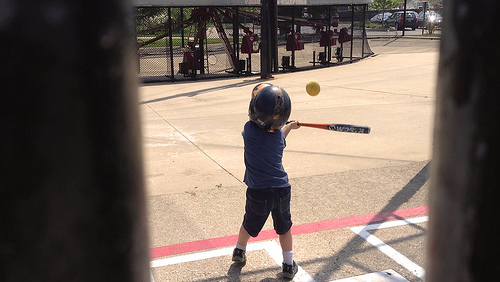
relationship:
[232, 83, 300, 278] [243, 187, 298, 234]
boy wearing shorts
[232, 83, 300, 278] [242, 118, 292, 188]
boy wearing shirt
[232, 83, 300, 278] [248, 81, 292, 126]
boy has helmet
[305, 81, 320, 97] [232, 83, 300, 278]
ball near boy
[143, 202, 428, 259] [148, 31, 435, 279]
line on ground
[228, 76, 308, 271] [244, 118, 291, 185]
boy has shirt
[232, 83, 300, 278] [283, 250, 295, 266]
boy has sock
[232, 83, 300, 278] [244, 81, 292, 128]
boy has helmet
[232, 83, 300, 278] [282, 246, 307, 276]
boy has socks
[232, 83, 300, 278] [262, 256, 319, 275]
boy has shoes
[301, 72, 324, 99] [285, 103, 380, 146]
ball and bat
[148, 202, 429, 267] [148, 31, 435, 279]
line painted on ground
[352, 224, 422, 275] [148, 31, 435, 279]
line painted on ground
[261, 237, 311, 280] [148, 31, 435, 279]
line painted on ground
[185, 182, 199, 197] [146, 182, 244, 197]
plant growing through crack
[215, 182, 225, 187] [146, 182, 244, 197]
plant growing through crack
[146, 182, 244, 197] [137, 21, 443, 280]
crack in ground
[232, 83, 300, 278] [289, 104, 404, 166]
boy holding bat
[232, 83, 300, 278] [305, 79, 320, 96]
boy hitting ball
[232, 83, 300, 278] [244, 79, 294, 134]
boy wearing a helmet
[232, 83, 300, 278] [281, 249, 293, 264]
boy has on sock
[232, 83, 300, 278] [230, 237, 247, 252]
boy has on sock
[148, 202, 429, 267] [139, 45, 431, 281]
line on court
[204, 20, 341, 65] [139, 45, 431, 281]
fence around court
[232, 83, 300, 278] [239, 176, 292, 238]
boy wearing shorts